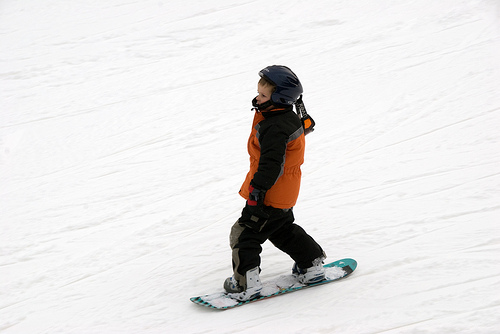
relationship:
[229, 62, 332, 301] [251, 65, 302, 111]
child wearing head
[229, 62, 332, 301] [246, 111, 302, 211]
child wearing coat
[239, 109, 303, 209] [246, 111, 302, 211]
coat on coat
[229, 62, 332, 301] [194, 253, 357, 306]
child riding snowboard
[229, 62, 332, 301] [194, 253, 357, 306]
child on snowboard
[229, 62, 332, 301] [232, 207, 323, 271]
child wearing pants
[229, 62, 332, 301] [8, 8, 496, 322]
child on mountain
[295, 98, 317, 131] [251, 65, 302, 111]
goggles on head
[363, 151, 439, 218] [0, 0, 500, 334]
tracks in mountain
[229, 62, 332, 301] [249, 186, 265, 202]
child wearing glove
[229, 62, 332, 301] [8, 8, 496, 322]
child snowboarding on mountain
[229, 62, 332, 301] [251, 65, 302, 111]
boy has head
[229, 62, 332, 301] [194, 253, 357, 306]
boy riding snowboard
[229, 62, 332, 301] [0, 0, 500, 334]
boy on mountain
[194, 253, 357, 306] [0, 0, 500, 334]
snowboard on mountain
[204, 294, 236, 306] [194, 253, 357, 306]
snow on snowboard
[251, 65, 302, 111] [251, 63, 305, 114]
head on head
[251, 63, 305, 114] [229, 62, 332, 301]
head on boy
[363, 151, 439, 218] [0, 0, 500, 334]
tracks on mountain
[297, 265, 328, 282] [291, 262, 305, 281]
clamp for boot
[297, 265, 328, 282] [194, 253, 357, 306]
clamp on snowboard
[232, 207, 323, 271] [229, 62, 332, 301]
pants on boy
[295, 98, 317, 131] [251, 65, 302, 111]
goggles hanging from head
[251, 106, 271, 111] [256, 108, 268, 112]
strap for chin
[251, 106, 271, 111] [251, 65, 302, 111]
strap on head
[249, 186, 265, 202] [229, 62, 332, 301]
gloves on boy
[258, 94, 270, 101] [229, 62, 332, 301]
eye on boy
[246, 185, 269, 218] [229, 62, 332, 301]
glove on boy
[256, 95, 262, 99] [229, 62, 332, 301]
nose on boy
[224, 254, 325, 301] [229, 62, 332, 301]
boots on boy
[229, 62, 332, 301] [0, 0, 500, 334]
boy in mountain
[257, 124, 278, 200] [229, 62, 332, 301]
arm on boy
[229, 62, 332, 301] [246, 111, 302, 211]
boy wearing coat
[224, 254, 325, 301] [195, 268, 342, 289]
boots on board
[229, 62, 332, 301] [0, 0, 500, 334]
person in mountain